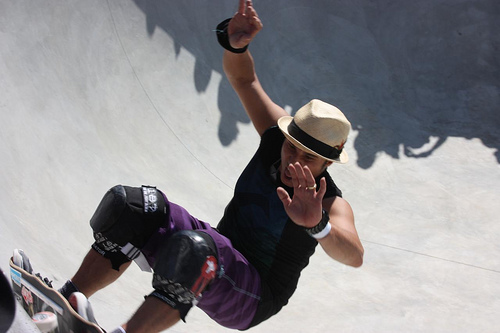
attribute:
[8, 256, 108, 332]
skateboard — here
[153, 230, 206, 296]
pad — black, knee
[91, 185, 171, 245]
pad — black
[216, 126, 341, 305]
top — black, sleeveless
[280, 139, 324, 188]
face — shaded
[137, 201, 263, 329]
shorts — purple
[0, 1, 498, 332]
wall — gray